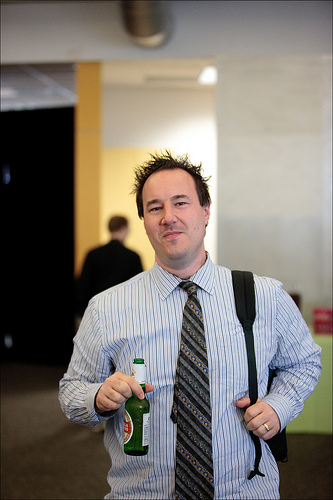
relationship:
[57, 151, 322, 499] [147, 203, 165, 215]
man has eye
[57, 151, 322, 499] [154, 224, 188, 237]
man has stubble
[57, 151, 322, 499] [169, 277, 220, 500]
man wearing tie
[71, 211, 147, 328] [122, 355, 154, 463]
man holding bottle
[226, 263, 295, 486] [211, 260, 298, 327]
back pack hanging on left shoulder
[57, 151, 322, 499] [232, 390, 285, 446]
man has hand